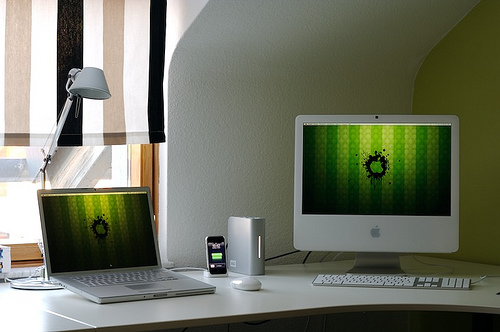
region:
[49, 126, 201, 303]
the computer is white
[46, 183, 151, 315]
the computer is white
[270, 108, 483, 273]
computer on a desk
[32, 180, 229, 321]
laptop on a desk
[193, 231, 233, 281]
cell phone on a desk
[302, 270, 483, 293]
computer keyboard on a desk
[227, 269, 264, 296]
computer mouse on a desk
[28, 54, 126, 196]
a white desk lamp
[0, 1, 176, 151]
curtain in front of a window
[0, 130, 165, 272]
window with wooden frame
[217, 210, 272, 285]
computer on a desk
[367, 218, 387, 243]
logo on a computer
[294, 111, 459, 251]
white desktop compute monitor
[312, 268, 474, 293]
white and silver desktop computer keyboard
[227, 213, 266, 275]
portable silver computer hard drive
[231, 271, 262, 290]
white cordless computing mouse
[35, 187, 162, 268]
laptop computer monitor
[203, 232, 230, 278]
charging smart phone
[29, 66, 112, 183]
adjustable white desk lamp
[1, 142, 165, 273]
closed wooden framed window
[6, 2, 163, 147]
striped black white and brown window shade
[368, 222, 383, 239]
gray apple computer logo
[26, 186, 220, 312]
white Apple laptop computer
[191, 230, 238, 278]
cellphone on a charging stand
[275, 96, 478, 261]
white Apple computer monitor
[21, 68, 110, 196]
white desk lamp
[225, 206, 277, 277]
white external hard drive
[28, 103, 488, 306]
desk with Apple products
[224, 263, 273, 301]
white computer mouse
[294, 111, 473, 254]
computer monitor with green background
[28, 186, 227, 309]
laptop with a green background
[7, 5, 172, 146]
brown, white and black window drapes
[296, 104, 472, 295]
larger computer on right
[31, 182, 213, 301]
smaller computer on left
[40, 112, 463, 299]
two identical screen savers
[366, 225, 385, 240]
apple logo on desktop monitor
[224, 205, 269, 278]
desktop system box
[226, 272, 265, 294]
white mouse next to laptop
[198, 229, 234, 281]
iPod touch sitting charger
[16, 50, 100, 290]
white lamp just behind laptop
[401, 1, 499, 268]
yellow side wall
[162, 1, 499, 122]
curved overhang at top of wall